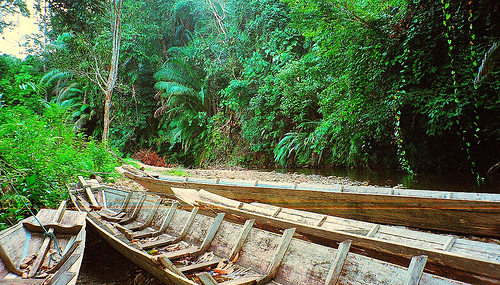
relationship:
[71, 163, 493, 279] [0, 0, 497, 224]
boats in forest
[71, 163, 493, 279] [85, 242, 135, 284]
boats on ground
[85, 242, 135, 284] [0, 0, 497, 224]
ground in forest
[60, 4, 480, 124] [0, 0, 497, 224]
trees in forest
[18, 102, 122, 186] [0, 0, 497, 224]
plants in forest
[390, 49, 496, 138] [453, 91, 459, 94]
vines have leave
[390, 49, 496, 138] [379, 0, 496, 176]
vines on tree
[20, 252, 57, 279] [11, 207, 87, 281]
debsris inside boat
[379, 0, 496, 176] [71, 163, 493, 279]
tree behind boats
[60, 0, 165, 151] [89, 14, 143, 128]
trees with leaves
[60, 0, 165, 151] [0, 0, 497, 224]
trees in forest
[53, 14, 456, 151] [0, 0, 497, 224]
features in forest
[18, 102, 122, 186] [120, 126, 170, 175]
plants beside path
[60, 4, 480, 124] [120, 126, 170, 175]
trees besides path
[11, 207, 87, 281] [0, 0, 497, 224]
boat in forest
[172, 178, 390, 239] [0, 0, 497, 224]
boat in forest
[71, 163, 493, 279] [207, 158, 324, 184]
boats on shore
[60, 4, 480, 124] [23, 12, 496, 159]
trees in forest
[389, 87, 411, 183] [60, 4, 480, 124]
ivy on trees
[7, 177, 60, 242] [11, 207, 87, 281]
rope tying boat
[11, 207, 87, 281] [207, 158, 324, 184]
boat tied to shore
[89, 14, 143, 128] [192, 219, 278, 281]
leaves on floor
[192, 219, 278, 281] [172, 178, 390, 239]
floor on boat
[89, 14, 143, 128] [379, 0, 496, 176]
leaves on tree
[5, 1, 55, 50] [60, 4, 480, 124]
sky peeking through trees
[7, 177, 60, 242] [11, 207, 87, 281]
rope holding boat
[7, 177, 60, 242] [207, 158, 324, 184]
rope holding shore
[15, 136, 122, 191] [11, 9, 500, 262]
vegetation left on picture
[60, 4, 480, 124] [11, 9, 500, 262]
trees upper portion of picture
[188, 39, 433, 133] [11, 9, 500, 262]
brush upper portion of picture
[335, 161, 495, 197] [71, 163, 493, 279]
water near boats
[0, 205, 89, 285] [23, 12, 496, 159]
boat in forest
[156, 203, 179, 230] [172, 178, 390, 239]
slats in boat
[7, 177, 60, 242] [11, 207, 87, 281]
rope in boat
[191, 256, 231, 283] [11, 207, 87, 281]
leaves in boat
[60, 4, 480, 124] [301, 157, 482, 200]
trees along river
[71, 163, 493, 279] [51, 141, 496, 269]
boats in field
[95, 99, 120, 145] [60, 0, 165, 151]
trunk of trees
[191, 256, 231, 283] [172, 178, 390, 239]
leaves inside boat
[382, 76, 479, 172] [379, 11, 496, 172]
vine hanging from tree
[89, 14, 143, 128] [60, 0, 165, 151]
leaves are from trees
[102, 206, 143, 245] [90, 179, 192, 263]
pieces in boat